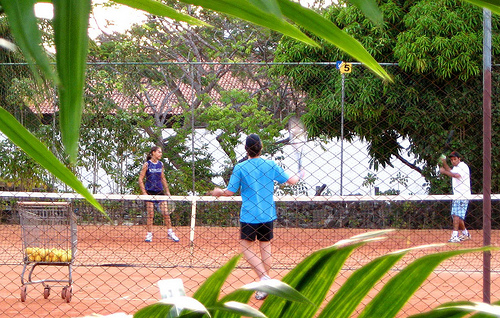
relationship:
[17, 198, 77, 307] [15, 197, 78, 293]
cart for shopping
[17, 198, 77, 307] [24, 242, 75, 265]
cart holding balls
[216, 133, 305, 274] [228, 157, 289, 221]
person has shirt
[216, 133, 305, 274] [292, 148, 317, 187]
person has racket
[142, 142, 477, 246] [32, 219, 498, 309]
people on court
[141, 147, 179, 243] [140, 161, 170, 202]
girl in shirt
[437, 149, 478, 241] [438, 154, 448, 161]
man has ball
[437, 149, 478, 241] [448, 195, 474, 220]
man has shorts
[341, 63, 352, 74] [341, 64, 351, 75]
sign has number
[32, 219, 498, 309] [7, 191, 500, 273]
court has net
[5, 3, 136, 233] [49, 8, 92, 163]
plant has leaves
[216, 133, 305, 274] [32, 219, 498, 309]
person on court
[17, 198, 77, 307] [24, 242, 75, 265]
cart has balls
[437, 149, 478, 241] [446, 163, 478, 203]
man wearing shirt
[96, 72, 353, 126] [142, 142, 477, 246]
fence behind people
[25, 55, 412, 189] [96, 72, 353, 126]
building behind fence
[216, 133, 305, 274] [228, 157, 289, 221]
person wearing shirt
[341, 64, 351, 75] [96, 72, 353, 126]
number on fence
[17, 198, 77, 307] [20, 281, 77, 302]
cart has wheels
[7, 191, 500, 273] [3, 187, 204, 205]
net has top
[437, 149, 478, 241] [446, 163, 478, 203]
man has shirt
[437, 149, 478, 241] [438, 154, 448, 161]
man serving ball